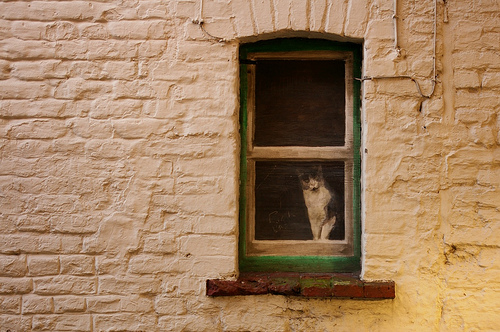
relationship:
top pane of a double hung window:
[166, 52, 366, 175] [235, 40, 359, 273]